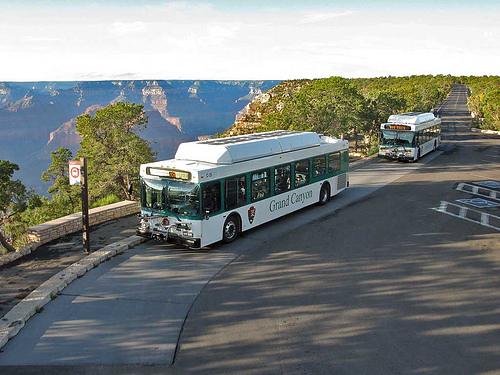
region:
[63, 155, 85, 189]
Red and white traffic sign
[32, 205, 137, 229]
Raised cobblestone portion above the walkway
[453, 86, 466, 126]
Road way off in the distance behind the second bus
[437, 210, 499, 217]
First set of white diagonal markings on the pavement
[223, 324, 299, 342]
One of the sunny portions of the road between the shadows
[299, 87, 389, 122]
Large expanse of trees in the background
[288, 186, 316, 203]
The word 'Canyon' on the side of the bus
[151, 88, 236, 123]
Majestic mountains in the background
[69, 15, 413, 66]
Brilliantly bright sky in the background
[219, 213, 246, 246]
Front tire of the first bus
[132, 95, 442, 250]
Two buses are on the road.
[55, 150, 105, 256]
A sign with a bus symbol on it.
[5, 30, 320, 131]
The Grand Canyon.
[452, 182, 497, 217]
A handicap parking space.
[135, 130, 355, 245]
A white and green bus.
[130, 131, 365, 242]
A bus headed towards the Grand Canyon.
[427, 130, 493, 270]
Parking spaces.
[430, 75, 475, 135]
A road lined with trees.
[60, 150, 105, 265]
A sign attached to a wooden post.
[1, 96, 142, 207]
Trees on the edge of the canyon.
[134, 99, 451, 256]
Two buses are parked on the street.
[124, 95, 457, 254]
The buses are green and white.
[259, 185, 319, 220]
The bus says Grand Canyon.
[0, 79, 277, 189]
The Grand Canyon is visible in the background.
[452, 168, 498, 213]
The parking spaces are for handicapped people.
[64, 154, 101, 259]
A sign is on the street.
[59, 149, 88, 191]
The sign is red and white.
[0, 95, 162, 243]
Trees grow next to the street.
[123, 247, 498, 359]
Sunlight shines on the street.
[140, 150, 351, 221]
The bus' windows are lined with green.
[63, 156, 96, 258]
Bus sign on post on sidewalk.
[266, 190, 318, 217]
Grand Canyon advertisement on bus.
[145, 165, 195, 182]
Marquee display on front of first bus.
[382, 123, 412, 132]
Marquee display on front of second bus.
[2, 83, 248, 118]
Mountains in the background.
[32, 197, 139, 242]
Brick wall on the side of the sidewalk.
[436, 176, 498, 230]
Handicap parking spots on street.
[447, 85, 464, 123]
Yellow paint dividing sides of streets in background.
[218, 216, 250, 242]
Front wheel of first bus.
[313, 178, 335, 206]
Back wheel of first bus.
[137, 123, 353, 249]
a white with green trim bus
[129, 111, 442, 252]
two buses from the same company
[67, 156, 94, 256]
a sign on a wood pole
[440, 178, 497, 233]
two handicap parking signs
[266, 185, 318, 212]
Grand Canyon written on side of bus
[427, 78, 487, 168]
a road surrounded by the trees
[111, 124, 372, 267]
a bus pulling over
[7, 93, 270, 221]
view of the grand canyon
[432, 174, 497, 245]
white lines showing where to park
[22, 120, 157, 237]
a few green trees